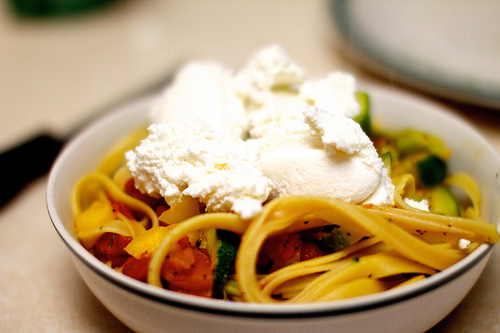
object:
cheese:
[228, 195, 261, 221]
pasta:
[310, 275, 389, 303]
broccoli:
[412, 153, 451, 187]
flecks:
[348, 256, 363, 264]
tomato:
[149, 246, 208, 289]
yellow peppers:
[123, 226, 173, 260]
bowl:
[42, 78, 500, 333]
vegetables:
[210, 239, 238, 299]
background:
[0, 0, 500, 332]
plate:
[319, 0, 500, 113]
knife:
[57, 53, 199, 141]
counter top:
[0, 0, 500, 333]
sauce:
[464, 137, 495, 167]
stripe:
[67, 172, 160, 232]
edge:
[79, 139, 86, 145]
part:
[107, 16, 127, 31]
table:
[0, 0, 500, 332]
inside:
[110, 124, 135, 138]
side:
[101, 294, 143, 319]